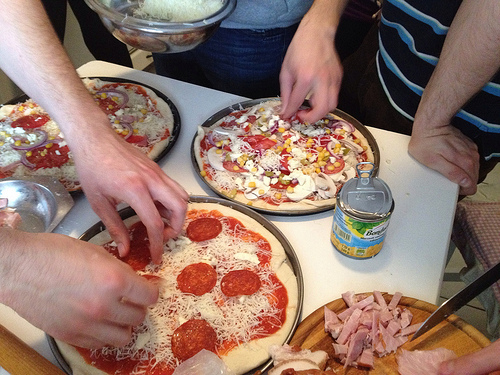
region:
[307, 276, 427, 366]
pieces of cut up ham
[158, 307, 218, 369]
a single piece of pepperoni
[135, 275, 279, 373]
pepperoni and cheese pizza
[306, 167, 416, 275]
a can of pineapple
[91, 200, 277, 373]
a perpperoni and cheese pizza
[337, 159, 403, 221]
a silver lid for a pop top can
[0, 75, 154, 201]
purple onion on pizza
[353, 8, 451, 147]
blue and white striped shirt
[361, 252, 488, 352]
a silver sharp knife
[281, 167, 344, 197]
white mushrooms on a pizza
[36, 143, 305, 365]
the pizza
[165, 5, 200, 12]
bowl full of cheese.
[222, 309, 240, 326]
cheese on the pizza.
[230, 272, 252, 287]
pepperoni on the pizza.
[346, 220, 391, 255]
aluminum can on the table.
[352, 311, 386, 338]
ham on the plate.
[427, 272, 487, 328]
knife near the ham.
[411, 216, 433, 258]
shadow on the table.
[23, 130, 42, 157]
onions on the pizza.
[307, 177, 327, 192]
mushrooms on the pizza.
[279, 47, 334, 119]
person's hand near the pizza.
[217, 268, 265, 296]
a slice of tomato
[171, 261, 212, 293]
a slice of tomato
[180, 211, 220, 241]
a slice of tomato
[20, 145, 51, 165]
a slice of tomato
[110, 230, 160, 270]
a slice of tomato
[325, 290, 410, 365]
small pieces of meat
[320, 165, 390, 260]
a tin of canned food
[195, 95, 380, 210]
a plate of pizza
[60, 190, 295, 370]
a plate of pizza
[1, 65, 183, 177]
a plate of pizza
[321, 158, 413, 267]
an open can on the table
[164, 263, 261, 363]
sparse placement of pepperoni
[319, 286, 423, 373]
pieces of chopped ham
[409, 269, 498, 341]
a knife for chopping ingredients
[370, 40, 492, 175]
a striped shirt on a person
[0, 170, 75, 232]
a container of toppings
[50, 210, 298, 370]
a pepperoni pizza in a small pan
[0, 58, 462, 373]
a small white table top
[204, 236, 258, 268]
grated cheese on the pizza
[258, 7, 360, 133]
a left hand working on a pizza